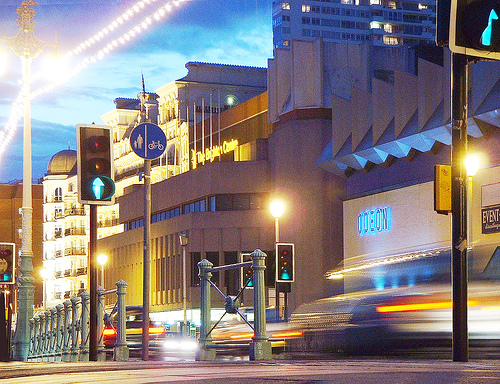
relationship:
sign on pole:
[127, 121, 167, 161] [140, 159, 150, 362]